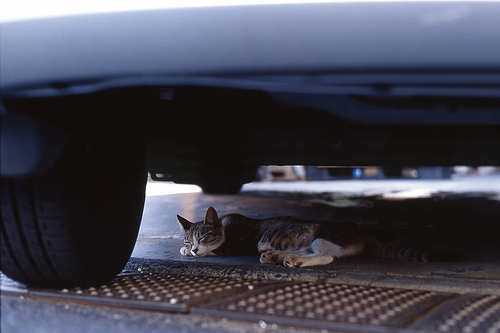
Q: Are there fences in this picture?
A: No, there are no fences.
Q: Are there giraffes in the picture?
A: No, there are no giraffes.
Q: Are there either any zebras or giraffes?
A: No, there are no giraffes or zebras.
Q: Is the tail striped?
A: Yes, the tail is striped.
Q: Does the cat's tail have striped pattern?
A: Yes, the tail is striped.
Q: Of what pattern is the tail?
A: The tail is striped.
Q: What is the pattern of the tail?
A: The tail is striped.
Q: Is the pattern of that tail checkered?
A: No, the tail is striped.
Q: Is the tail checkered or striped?
A: The tail is striped.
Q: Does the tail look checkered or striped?
A: The tail is striped.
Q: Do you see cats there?
A: Yes, there is a cat.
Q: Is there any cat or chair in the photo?
A: Yes, there is a cat.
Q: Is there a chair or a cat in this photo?
A: Yes, there is a cat.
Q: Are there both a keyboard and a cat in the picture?
A: No, there is a cat but no keyboards.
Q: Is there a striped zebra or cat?
A: Yes, there is a striped cat.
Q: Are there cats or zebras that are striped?
A: Yes, the cat is striped.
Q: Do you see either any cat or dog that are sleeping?
A: Yes, the cat is sleeping.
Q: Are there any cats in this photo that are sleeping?
A: Yes, there is a cat that is sleeping.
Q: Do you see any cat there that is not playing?
A: Yes, there is a cat that is sleeping .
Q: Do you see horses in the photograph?
A: No, there are no horses.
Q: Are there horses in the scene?
A: No, there are no horses.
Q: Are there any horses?
A: No, there are no horses.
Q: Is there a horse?
A: No, there are no horses.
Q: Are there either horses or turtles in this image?
A: No, there are no horses or turtles.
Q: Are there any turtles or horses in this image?
A: No, there are no horses or turtles.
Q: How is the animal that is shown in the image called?
A: The animal is a cat.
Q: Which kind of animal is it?
A: The animal is a cat.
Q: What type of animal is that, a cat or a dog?
A: That is a cat.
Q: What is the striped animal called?
A: The animal is a cat.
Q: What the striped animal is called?
A: The animal is a cat.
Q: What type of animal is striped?
A: The animal is a cat.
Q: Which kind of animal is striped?
A: The animal is a cat.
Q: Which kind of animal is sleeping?
A: The animal is a cat.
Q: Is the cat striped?
A: Yes, the cat is striped.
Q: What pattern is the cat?
A: The cat is striped.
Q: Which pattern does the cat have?
A: The cat has striped pattern.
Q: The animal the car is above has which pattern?
A: The cat is striped.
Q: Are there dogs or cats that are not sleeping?
A: No, there is a cat but it is sleeping.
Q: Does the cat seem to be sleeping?
A: Yes, the cat is sleeping.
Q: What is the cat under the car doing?
A: The cat is sleeping.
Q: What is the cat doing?
A: The cat is sleeping.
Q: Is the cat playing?
A: No, the cat is sleeping.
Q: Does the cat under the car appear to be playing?
A: No, the cat is sleeping.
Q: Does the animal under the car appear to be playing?
A: No, the cat is sleeping.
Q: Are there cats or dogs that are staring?
A: No, there is a cat but it is sleeping.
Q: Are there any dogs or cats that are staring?
A: No, there is a cat but it is sleeping.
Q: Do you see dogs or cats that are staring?
A: No, there is a cat but it is sleeping.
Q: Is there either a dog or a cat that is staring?
A: No, there is a cat but it is sleeping.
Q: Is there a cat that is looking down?
A: No, there is a cat but it is sleeping.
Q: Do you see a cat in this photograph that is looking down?
A: No, there is a cat but it is sleeping.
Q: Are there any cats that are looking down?
A: No, there is a cat but it is sleeping.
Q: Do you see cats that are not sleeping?
A: No, there is a cat but it is sleeping.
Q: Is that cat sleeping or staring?
A: The cat is sleeping.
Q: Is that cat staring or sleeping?
A: The cat is sleeping.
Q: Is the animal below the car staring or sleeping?
A: The cat is sleeping.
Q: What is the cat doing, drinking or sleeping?
A: The cat is sleeping.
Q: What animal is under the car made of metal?
A: The cat is under the car.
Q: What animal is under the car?
A: The cat is under the car.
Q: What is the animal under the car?
A: The animal is a cat.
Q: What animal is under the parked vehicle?
A: The animal is a cat.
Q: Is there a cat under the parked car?
A: Yes, there is a cat under the car.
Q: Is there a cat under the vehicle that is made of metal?
A: Yes, there is a cat under the car.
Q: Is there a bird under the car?
A: No, there is a cat under the car.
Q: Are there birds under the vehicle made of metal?
A: No, there is a cat under the car.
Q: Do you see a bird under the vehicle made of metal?
A: No, there is a cat under the car.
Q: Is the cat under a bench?
A: No, the cat is under a car.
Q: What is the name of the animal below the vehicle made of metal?
A: The animal is a cat.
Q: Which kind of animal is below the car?
A: The animal is a cat.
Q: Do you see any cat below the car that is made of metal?
A: Yes, there is a cat below the car.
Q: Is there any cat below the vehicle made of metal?
A: Yes, there is a cat below the car.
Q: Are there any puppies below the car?
A: No, there is a cat below the car.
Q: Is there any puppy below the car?
A: No, there is a cat below the car.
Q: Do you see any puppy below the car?
A: No, there is a cat below the car.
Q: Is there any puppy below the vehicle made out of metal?
A: No, there is a cat below the car.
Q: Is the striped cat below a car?
A: Yes, the cat is below a car.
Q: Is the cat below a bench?
A: No, the cat is below a car.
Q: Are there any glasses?
A: No, there are no glasses.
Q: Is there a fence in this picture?
A: No, there are no fences.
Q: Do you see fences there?
A: No, there are no fences.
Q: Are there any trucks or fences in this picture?
A: No, there are no fences or trucks.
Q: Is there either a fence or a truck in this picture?
A: No, there are no fences or trucks.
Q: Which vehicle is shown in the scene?
A: The vehicle is a car.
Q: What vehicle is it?
A: The vehicle is a car.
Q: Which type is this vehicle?
A: This is a car.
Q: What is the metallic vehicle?
A: The vehicle is a car.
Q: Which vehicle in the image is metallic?
A: The vehicle is a car.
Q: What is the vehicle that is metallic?
A: The vehicle is a car.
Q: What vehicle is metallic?
A: The vehicle is a car.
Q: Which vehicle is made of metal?
A: The vehicle is a car.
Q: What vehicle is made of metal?
A: The vehicle is a car.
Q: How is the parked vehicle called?
A: The vehicle is a car.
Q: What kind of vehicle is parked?
A: The vehicle is a car.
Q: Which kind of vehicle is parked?
A: The vehicle is a car.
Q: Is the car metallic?
A: Yes, the car is metallic.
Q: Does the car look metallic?
A: Yes, the car is metallic.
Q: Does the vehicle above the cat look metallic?
A: Yes, the car is metallic.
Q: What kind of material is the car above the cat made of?
A: The car is made of metal.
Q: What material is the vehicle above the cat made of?
A: The car is made of metal.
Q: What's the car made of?
A: The car is made of metal.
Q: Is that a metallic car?
A: Yes, that is a metallic car.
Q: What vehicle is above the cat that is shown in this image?
A: The vehicle is a car.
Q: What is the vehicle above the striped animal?
A: The vehicle is a car.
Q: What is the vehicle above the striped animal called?
A: The vehicle is a car.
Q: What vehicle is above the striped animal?
A: The vehicle is a car.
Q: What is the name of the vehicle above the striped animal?
A: The vehicle is a car.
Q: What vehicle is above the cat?
A: The vehicle is a car.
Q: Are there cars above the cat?
A: Yes, there is a car above the cat.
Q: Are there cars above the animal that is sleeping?
A: Yes, there is a car above the cat.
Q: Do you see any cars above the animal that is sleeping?
A: Yes, there is a car above the cat.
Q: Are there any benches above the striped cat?
A: No, there is a car above the cat.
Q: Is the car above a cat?
A: Yes, the car is above a cat.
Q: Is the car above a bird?
A: No, the car is above a cat.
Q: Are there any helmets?
A: No, there are no helmets.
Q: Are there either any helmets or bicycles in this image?
A: No, there are no helmets or bicycles.